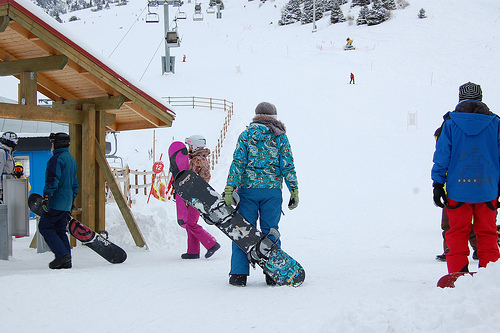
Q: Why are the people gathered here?
A: To participate in winter sports.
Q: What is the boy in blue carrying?
A: A snowboard.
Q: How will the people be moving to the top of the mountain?
A: On the ski lift.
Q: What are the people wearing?
A: Ski pants and parkas.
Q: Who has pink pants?
A: A girl.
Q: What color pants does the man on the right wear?
A: Red.